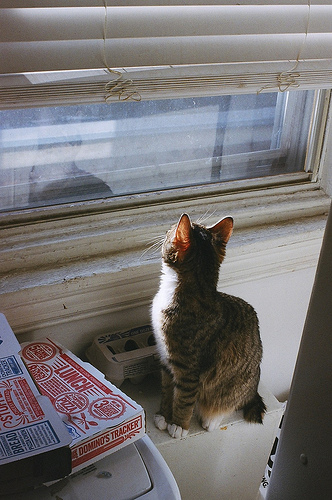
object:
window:
[0, 82, 316, 218]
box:
[22, 334, 158, 486]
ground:
[259, 113, 274, 135]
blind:
[0, 1, 332, 108]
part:
[85, 317, 158, 388]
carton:
[85, 320, 160, 387]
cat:
[149, 213, 267, 438]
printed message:
[56, 410, 148, 460]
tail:
[244, 394, 268, 424]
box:
[0, 304, 72, 498]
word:
[50, 364, 89, 392]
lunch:
[51, 361, 95, 402]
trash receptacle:
[46, 432, 186, 498]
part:
[114, 425, 130, 432]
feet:
[150, 409, 195, 450]